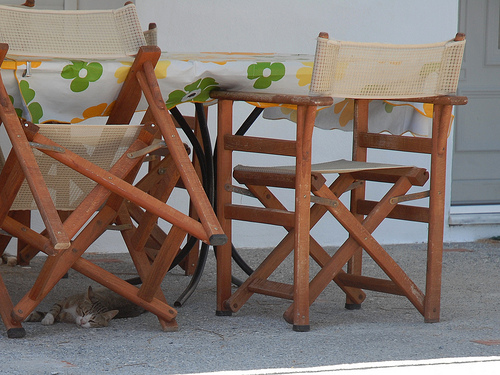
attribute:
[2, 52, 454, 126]
tablecloth — white, gray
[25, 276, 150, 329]
cat — gray, sleeping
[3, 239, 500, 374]
ground — gray, concrete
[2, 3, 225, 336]
chair — canvas, wood, beige, tilted, leaning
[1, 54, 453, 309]
table — black, metal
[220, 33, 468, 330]
chair — wood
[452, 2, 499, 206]
door — gray, white, grey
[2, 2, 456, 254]
wall — white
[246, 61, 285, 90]
flower — green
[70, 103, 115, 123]
flower — yellow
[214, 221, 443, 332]
legs — wood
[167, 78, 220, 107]
flower — green